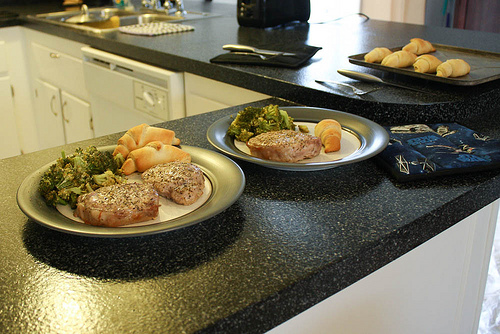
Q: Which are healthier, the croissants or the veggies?
A: The veggies are healthier than the croissants.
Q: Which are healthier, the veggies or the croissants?
A: The veggies are healthier than the croissants.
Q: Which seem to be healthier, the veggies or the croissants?
A: The veggies are healthier than the croissants.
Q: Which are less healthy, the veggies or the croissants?
A: The croissants are less healthy than the veggies.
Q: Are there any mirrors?
A: No, there are no mirrors.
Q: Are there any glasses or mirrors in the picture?
A: No, there are no mirrors or glasses.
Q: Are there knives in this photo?
A: Yes, there is a knife.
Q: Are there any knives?
A: Yes, there is a knife.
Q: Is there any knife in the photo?
A: Yes, there is a knife.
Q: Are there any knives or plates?
A: Yes, there is a knife.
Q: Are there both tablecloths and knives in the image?
A: No, there is a knife but no tablecloths.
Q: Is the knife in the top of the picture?
A: Yes, the knife is in the top of the image.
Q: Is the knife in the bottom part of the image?
A: No, the knife is in the top of the image.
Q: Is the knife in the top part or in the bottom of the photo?
A: The knife is in the top of the image.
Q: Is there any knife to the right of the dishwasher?
A: Yes, there is a knife to the right of the dishwasher.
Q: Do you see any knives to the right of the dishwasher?
A: Yes, there is a knife to the right of the dishwasher.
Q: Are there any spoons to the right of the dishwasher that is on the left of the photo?
A: No, there is a knife to the right of the dish washer.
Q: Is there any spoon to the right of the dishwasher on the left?
A: No, there is a knife to the right of the dish washer.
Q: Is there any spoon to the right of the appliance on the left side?
A: No, there is a knife to the right of the dish washer.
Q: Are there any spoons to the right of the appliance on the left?
A: No, there is a knife to the right of the dish washer.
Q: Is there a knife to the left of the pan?
A: Yes, there is a knife to the left of the pan.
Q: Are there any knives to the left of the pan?
A: Yes, there is a knife to the left of the pan.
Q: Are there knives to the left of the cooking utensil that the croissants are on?
A: Yes, there is a knife to the left of the pan.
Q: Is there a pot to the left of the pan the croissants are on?
A: No, there is a knife to the left of the pan.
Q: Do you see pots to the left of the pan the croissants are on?
A: No, there is a knife to the left of the pan.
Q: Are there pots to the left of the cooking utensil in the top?
A: No, there is a knife to the left of the pan.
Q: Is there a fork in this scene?
A: Yes, there is a fork.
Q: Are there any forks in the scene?
A: Yes, there is a fork.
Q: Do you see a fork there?
A: Yes, there is a fork.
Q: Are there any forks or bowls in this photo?
A: Yes, there is a fork.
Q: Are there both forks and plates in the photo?
A: Yes, there are both a fork and a plate.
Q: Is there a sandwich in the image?
A: No, there are no sandwiches.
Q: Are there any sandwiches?
A: No, there are no sandwiches.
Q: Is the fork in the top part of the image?
A: Yes, the fork is in the top of the image.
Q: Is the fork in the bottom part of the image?
A: No, the fork is in the top of the image.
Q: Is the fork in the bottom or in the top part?
A: The fork is in the top of the image.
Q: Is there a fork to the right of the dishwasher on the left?
A: Yes, there is a fork to the right of the dishwasher.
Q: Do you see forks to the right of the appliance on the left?
A: Yes, there is a fork to the right of the dishwasher.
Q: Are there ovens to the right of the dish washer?
A: No, there is a fork to the right of the dish washer.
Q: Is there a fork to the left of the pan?
A: Yes, there is a fork to the left of the pan.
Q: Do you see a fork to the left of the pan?
A: Yes, there is a fork to the left of the pan.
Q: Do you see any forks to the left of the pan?
A: Yes, there is a fork to the left of the pan.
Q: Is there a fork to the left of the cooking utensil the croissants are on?
A: Yes, there is a fork to the left of the pan.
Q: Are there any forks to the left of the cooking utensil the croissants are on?
A: Yes, there is a fork to the left of the pan.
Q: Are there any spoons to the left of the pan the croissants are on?
A: No, there is a fork to the left of the pan.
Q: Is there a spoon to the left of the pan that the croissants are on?
A: No, there is a fork to the left of the pan.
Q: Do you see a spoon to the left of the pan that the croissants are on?
A: No, there is a fork to the left of the pan.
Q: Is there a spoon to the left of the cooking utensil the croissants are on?
A: No, there is a fork to the left of the pan.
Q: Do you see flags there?
A: No, there are no flags.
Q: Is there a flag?
A: No, there are no flags.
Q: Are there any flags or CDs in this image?
A: No, there are no flags or cds.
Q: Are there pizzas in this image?
A: No, there are no pizzas.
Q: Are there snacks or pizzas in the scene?
A: No, there are no pizzas or snacks.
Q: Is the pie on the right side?
A: Yes, the pie is on the right of the image.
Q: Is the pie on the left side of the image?
A: No, the pie is on the right of the image.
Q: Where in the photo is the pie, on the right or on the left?
A: The pie is on the right of the image.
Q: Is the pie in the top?
A: Yes, the pie is in the top of the image.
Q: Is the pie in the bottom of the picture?
A: No, the pie is in the top of the image.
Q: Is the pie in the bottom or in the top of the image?
A: The pie is in the top of the image.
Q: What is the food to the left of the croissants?
A: The food is a pie.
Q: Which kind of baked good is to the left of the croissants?
A: The food is a pie.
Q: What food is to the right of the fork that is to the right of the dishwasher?
A: The food is a pie.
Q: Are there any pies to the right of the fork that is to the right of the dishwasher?
A: Yes, there is a pie to the right of the fork.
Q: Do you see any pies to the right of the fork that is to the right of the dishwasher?
A: Yes, there is a pie to the right of the fork.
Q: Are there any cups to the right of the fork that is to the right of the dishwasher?
A: No, there is a pie to the right of the fork.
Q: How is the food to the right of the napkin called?
A: The food is a pie.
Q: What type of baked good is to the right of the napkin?
A: The food is a pie.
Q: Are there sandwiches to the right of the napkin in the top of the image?
A: No, there is a pie to the right of the napkin.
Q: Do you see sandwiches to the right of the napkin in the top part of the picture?
A: No, there is a pie to the right of the napkin.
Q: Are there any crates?
A: No, there are no crates.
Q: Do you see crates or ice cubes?
A: No, there are no crates or ice cubes.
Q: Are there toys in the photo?
A: No, there are no toys.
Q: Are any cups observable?
A: No, there are no cups.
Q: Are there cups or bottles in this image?
A: No, there are no cups or bottles.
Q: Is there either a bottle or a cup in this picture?
A: No, there are no cups or bottles.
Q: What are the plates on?
A: The plates are on the counter.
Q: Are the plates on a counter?
A: Yes, the plates are on a counter.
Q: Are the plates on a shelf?
A: No, the plates are on a counter.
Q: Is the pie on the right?
A: Yes, the pie is on the right of the image.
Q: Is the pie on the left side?
A: No, the pie is on the right of the image.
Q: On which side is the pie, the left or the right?
A: The pie is on the right of the image.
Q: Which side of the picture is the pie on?
A: The pie is on the right of the image.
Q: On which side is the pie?
A: The pie is on the right of the image.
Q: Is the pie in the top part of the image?
A: Yes, the pie is in the top of the image.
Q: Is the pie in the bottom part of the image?
A: No, the pie is in the top of the image.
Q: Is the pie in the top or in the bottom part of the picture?
A: The pie is in the top of the image.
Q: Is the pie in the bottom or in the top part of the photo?
A: The pie is in the top of the image.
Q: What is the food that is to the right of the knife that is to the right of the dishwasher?
A: The food is a pie.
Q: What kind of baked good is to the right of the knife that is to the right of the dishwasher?
A: The food is a pie.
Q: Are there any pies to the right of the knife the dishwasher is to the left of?
A: Yes, there is a pie to the right of the knife.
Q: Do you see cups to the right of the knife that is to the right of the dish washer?
A: No, there is a pie to the right of the knife.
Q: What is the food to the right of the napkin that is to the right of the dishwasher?
A: The food is a pie.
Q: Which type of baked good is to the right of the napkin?
A: The food is a pie.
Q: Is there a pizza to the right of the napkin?
A: No, there is a pie to the right of the napkin.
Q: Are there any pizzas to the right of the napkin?
A: No, there is a pie to the right of the napkin.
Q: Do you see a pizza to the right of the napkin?
A: No, there is a pie to the right of the napkin.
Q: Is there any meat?
A: Yes, there is meat.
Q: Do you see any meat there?
A: Yes, there is meat.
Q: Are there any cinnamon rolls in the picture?
A: No, there are no cinnamon rolls.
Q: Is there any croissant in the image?
A: Yes, there are croissants.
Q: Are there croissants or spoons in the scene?
A: Yes, there are croissants.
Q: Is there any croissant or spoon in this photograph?
A: Yes, there are croissants.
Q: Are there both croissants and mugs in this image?
A: No, there are croissants but no mugs.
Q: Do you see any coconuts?
A: No, there are no coconuts.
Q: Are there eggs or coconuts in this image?
A: No, there are no coconuts or eggs.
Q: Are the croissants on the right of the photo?
A: Yes, the croissants are on the right of the image.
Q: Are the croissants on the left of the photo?
A: No, the croissants are on the right of the image.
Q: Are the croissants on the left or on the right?
A: The croissants are on the right of the image.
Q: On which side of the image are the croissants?
A: The croissants are on the right of the image.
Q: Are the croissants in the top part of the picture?
A: Yes, the croissants are in the top of the image.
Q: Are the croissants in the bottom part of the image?
A: No, the croissants are in the top of the image.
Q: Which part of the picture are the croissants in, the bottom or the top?
A: The croissants are in the top of the image.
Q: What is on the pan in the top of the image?
A: The croissants are on the pan.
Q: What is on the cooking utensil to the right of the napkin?
A: The croissants are on the pan.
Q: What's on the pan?
A: The croissants are on the pan.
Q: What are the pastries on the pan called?
A: The pastries are croissants.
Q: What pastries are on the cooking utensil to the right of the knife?
A: The pastries are croissants.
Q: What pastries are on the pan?
A: The pastries are croissants.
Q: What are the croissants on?
A: The croissants are on the pan.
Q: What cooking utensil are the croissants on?
A: The croissants are on the pan.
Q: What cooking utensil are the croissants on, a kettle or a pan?
A: The croissants are on a pan.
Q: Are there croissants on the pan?
A: Yes, there are croissants on the pan.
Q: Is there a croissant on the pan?
A: Yes, there are croissants on the pan.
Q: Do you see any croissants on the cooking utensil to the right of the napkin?
A: Yes, there are croissants on the pan.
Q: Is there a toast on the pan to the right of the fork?
A: No, there are croissants on the pan.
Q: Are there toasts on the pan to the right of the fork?
A: No, there are croissants on the pan.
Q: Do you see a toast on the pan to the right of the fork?
A: No, there are croissants on the pan.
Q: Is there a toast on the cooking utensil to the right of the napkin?
A: No, there are croissants on the pan.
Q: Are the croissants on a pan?
A: Yes, the croissants are on a pan.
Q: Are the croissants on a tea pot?
A: No, the croissants are on a pan.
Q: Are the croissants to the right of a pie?
A: Yes, the croissants are to the right of a pie.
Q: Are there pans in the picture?
A: Yes, there is a pan.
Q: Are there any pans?
A: Yes, there is a pan.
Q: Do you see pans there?
A: Yes, there is a pan.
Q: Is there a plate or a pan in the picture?
A: Yes, there is a pan.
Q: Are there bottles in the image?
A: No, there are no bottles.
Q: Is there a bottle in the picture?
A: No, there are no bottles.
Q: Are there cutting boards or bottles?
A: No, there are no bottles or cutting boards.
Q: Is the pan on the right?
A: Yes, the pan is on the right of the image.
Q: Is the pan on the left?
A: No, the pan is on the right of the image.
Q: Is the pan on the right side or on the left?
A: The pan is on the right of the image.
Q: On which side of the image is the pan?
A: The pan is on the right of the image.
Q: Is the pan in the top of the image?
A: Yes, the pan is in the top of the image.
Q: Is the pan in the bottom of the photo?
A: No, the pan is in the top of the image.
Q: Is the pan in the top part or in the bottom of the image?
A: The pan is in the top of the image.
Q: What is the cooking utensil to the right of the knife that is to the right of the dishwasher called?
A: The cooking utensil is a pan.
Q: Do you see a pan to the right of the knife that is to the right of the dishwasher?
A: Yes, there is a pan to the right of the knife.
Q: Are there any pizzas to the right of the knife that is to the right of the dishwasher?
A: No, there is a pan to the right of the knife.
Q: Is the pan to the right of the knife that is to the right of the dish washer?
A: Yes, the pan is to the right of the knife.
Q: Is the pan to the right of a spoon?
A: No, the pan is to the right of the knife.